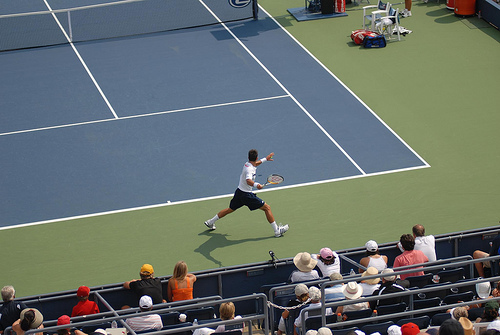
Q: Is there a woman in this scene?
A: Yes, there is a woman.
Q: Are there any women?
A: Yes, there is a woman.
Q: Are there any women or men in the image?
A: Yes, there is a woman.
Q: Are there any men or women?
A: Yes, there is a woman.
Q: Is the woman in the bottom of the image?
A: Yes, the woman is in the bottom of the image.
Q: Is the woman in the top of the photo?
A: No, the woman is in the bottom of the image.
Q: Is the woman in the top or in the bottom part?
A: The woman is in the bottom of the image.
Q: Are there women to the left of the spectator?
A: Yes, there is a woman to the left of the spectator.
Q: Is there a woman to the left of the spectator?
A: Yes, there is a woman to the left of the spectator.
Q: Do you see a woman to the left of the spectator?
A: Yes, there is a woman to the left of the spectator.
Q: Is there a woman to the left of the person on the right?
A: Yes, there is a woman to the left of the spectator.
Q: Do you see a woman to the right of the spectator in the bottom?
A: No, the woman is to the left of the spectator.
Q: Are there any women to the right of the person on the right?
A: No, the woman is to the left of the spectator.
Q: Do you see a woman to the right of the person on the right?
A: No, the woman is to the left of the spectator.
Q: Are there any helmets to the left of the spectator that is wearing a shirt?
A: No, there is a woman to the left of the spectator.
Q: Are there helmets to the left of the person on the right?
A: No, there is a woman to the left of the spectator.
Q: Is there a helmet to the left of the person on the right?
A: No, there is a woman to the left of the spectator.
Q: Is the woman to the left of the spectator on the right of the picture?
A: Yes, the woman is to the left of the spectator.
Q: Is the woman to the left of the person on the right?
A: Yes, the woman is to the left of the spectator.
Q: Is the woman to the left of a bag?
A: No, the woman is to the left of the spectator.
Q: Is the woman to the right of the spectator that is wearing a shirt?
A: No, the woman is to the left of the spectator.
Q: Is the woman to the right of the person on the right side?
A: No, the woman is to the left of the spectator.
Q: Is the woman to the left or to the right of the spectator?
A: The woman is to the left of the spectator.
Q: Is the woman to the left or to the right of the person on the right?
A: The woman is to the left of the spectator.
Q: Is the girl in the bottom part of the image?
A: Yes, the girl is in the bottom of the image.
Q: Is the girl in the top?
A: No, the girl is in the bottom of the image.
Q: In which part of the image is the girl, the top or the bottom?
A: The girl is in the bottom of the image.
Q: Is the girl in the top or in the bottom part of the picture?
A: The girl is in the bottom of the image.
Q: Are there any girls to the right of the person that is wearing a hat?
A: Yes, there is a girl to the right of the person.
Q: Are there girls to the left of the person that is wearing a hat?
A: No, the girl is to the right of the person.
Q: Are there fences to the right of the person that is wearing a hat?
A: No, there is a girl to the right of the person.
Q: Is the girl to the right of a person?
A: Yes, the girl is to the right of a person.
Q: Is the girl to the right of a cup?
A: No, the girl is to the right of a person.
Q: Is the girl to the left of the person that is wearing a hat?
A: No, the girl is to the right of the person.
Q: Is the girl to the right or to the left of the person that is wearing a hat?
A: The girl is to the right of the person.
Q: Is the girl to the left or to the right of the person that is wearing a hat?
A: The girl is to the right of the person.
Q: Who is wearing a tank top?
A: The girl is wearing a tank top.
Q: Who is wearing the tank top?
A: The girl is wearing a tank top.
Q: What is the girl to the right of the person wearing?
A: The girl is wearing a tank top.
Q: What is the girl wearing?
A: The girl is wearing a tank top.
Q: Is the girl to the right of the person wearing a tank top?
A: Yes, the girl is wearing a tank top.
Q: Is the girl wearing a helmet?
A: No, the girl is wearing a tank top.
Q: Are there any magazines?
A: No, there are no magazines.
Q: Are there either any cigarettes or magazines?
A: No, there are no magazines or cigarettes.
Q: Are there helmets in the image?
A: No, there are no helmets.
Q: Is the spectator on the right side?
A: Yes, the spectator is on the right of the image.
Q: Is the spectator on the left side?
A: No, the spectator is on the right of the image.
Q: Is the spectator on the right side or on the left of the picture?
A: The spectator is on the right of the image.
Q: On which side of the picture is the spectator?
A: The spectator is on the right of the image.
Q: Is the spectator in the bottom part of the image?
A: Yes, the spectator is in the bottom of the image.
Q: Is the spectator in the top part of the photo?
A: No, the spectator is in the bottom of the image.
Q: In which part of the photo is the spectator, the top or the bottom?
A: The spectator is in the bottom of the image.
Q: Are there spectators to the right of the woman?
A: Yes, there is a spectator to the right of the woman.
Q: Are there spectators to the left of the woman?
A: No, the spectator is to the right of the woman.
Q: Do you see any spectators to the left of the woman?
A: No, the spectator is to the right of the woman.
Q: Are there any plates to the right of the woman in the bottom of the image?
A: No, there is a spectator to the right of the woman.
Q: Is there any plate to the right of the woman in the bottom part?
A: No, there is a spectator to the right of the woman.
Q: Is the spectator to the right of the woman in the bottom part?
A: Yes, the spectator is to the right of the woman.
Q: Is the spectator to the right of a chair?
A: No, the spectator is to the right of the woman.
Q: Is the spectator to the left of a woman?
A: No, the spectator is to the right of a woman.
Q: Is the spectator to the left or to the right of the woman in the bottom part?
A: The spectator is to the right of the woman.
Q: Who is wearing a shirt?
A: The spectator is wearing a shirt.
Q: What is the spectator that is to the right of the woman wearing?
A: The spectator is wearing a shirt.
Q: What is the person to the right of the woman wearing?
A: The spectator is wearing a shirt.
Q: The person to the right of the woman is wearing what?
A: The spectator is wearing a shirt.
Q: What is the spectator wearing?
A: The spectator is wearing a shirt.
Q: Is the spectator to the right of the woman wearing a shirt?
A: Yes, the spectator is wearing a shirt.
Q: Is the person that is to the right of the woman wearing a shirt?
A: Yes, the spectator is wearing a shirt.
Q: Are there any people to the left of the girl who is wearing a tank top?
A: Yes, there is a person to the left of the girl.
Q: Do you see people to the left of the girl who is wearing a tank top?
A: Yes, there is a person to the left of the girl.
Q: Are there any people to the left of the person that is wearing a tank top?
A: Yes, there is a person to the left of the girl.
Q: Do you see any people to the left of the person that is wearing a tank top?
A: Yes, there is a person to the left of the girl.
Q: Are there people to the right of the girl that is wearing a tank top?
A: No, the person is to the left of the girl.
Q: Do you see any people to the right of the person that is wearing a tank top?
A: No, the person is to the left of the girl.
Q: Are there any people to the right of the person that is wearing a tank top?
A: No, the person is to the left of the girl.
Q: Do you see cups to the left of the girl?
A: No, there is a person to the left of the girl.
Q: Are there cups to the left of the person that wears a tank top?
A: No, there is a person to the left of the girl.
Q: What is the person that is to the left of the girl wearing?
A: The person is wearing a hat.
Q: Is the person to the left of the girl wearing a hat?
A: Yes, the person is wearing a hat.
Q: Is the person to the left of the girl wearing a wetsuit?
A: No, the person is wearing a hat.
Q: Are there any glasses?
A: No, there are no glasses.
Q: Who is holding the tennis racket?
A: The guy is holding the tennis racket.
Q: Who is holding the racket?
A: The guy is holding the tennis racket.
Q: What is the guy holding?
A: The guy is holding the tennis racket.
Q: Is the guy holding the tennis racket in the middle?
A: Yes, the guy is holding the tennis racket.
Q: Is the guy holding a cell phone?
A: No, the guy is holding the tennis racket.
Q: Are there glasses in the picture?
A: No, there are no glasses.